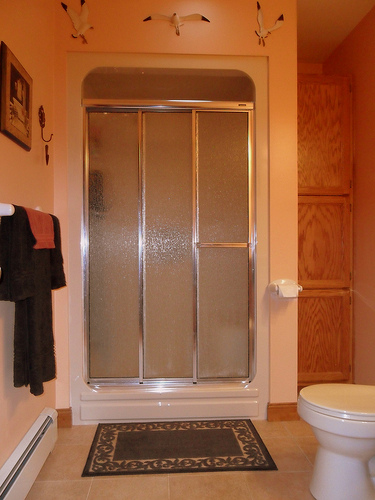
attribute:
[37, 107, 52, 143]
hook — wall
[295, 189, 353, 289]
cabinet — wooden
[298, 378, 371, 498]
toilet — white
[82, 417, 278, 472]
bath mat — large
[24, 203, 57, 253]
towel — black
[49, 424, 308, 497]
floor — tile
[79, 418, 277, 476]
mat — green, beige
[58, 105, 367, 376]
cabinet — brown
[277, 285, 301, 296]
tissue — roll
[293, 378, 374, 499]
toilet — white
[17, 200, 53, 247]
washcloth — pink